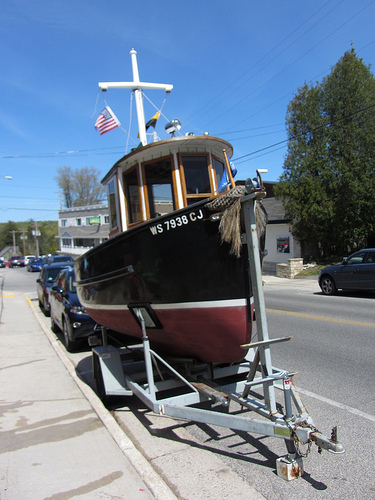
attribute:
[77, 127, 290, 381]
ship — here, brown, close, small, below, parked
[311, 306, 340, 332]
line — yellow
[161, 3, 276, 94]
sky — blue, high, sunny, bright, light, clear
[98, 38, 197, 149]
cross — White 